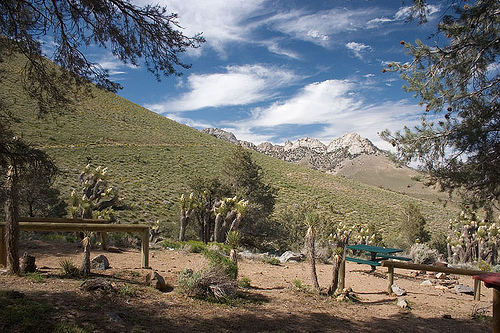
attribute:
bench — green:
[340, 240, 412, 272]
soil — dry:
[8, 235, 498, 331]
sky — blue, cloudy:
[244, 15, 379, 116]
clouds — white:
[266, 80, 351, 123]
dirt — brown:
[138, 244, 445, 308]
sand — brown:
[104, 246, 492, 301]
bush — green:
[171, 248, 259, 307]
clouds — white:
[186, 57, 370, 125]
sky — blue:
[0, 2, 498, 162]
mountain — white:
[273, 138, 328, 172]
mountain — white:
[325, 131, 372, 163]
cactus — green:
[64, 161, 129, 233]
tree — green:
[194, 175, 232, 246]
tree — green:
[224, 139, 278, 241]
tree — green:
[398, 200, 427, 260]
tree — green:
[1, 0, 208, 174]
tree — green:
[379, 1, 497, 208]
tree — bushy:
[210, 142, 279, 243]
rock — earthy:
[114, 263, 169, 285]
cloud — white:
[233, 74, 368, 135]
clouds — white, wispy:
[190, 72, 355, 122]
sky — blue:
[107, 27, 427, 129]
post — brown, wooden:
[12, 208, 151, 273]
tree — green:
[393, 9, 493, 209]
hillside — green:
[0, 36, 467, 250]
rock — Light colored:
[384, 290, 425, 324]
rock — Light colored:
[377, 268, 409, 295]